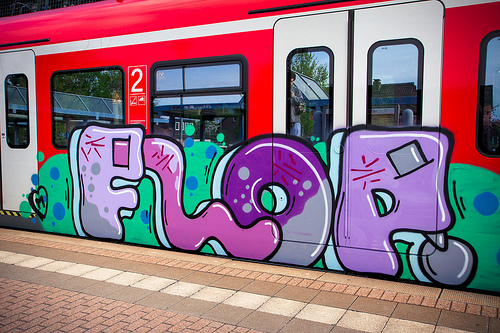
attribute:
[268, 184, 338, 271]
lettering — gray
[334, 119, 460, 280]
p letter — purple, graffiti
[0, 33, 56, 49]
lines — thin, black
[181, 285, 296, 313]
blocks — tan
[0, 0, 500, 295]
train — red, white and red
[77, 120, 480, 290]
lettering — purple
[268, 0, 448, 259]
doors — white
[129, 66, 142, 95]
number — white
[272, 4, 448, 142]
doors — white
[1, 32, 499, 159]
window — black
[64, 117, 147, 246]
letter f — purple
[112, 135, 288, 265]
letter l — pink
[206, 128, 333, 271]
letter o — purple, gray